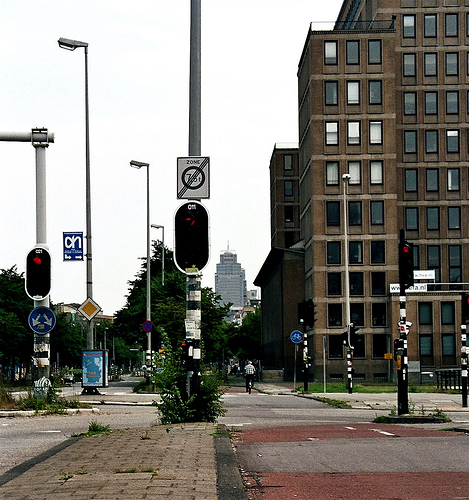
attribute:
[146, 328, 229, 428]
bush — green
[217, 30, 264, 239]
sky — cloudy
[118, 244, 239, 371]
tree — tall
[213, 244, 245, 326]
building — tall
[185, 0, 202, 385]
pole — iron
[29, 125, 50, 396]
pole — iron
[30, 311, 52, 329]
arrows — white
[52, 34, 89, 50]
light — big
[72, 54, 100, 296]
post — tall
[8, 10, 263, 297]
clouds — white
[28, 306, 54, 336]
sign — blue, circular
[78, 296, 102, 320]
sign — diamond shaped, white , yellow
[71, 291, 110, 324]
sign — yellow, white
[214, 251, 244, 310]
wall — white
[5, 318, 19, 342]
leaves — green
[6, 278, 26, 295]
leaves — green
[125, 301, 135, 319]
leaves — green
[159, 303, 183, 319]
leaves — green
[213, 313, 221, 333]
leaves — green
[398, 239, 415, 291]
black signal — traffic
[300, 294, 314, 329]
black signal — traffic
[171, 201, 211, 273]
black signal — traffic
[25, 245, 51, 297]
black signal — traffic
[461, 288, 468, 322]
black signal — traffic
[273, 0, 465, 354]
wall — brown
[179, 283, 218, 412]
pole — metal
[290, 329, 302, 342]
sign — blue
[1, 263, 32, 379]
tree — green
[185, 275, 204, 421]
post — black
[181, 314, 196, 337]
poster — white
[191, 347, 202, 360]
poster — white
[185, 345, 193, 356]
poster — white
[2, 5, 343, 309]
sky — cloudy, white